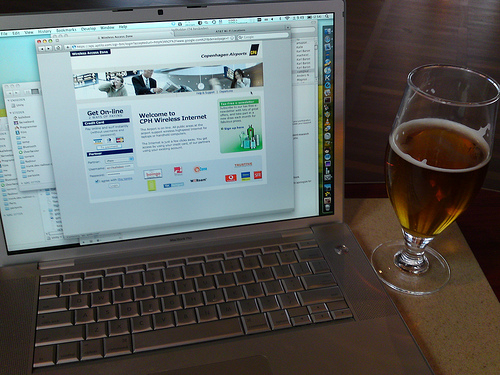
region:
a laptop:
[109, 75, 239, 236]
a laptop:
[184, 196, 279, 327]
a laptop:
[177, 243, 282, 358]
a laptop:
[163, 153, 296, 355]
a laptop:
[151, 161, 243, 297]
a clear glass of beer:
[362, 56, 498, 311]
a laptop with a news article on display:
[1, 1, 443, 373]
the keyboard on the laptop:
[19, 233, 379, 374]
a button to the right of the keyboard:
[326, 237, 355, 262]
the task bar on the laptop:
[310, 14, 345, 224]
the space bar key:
[119, 300, 263, 364]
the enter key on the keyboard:
[287, 263, 353, 293]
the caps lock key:
[21, 305, 88, 335]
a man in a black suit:
[120, 60, 176, 106]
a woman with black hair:
[224, 58, 260, 98]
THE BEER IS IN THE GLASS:
[367, 60, 498, 299]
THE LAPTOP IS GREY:
[3, 2, 438, 372]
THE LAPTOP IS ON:
[1, 0, 426, 373]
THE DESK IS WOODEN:
[331, 0, 497, 374]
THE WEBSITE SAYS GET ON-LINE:
[85, 107, 129, 119]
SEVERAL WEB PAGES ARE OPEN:
[1, 10, 337, 257]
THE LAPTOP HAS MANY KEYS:
[21, 235, 365, 374]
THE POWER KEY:
[328, 239, 351, 260]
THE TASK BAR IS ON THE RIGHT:
[318, 21, 334, 216]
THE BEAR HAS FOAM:
[386, 119, 493, 186]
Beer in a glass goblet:
[391, 133, 483, 243]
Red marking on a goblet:
[383, 157, 397, 173]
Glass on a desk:
[358, 200, 486, 350]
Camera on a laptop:
[155, 7, 166, 15]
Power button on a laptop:
[331, 240, 348, 254]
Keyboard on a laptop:
[37, 275, 333, 335]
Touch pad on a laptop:
[152, 355, 278, 371]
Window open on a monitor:
[29, 36, 300, 218]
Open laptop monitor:
[0, 5, 343, 223]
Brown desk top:
[343, 2, 498, 179]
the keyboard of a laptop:
[28, 225, 357, 373]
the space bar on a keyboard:
[129, 314, 246, 360]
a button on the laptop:
[331, 240, 351, 258]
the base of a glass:
[367, 233, 453, 300]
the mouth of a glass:
[402, 55, 499, 106]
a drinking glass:
[366, 62, 497, 297]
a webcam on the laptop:
[151, 6, 171, 18]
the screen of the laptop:
[0, 1, 350, 261]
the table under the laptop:
[330, 179, 498, 373]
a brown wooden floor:
[3, 0, 497, 301]